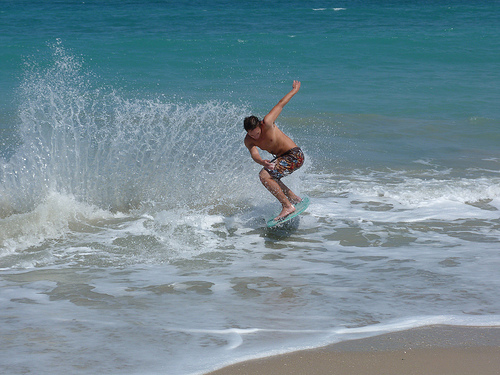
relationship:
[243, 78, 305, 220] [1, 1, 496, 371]
man surfing in ocean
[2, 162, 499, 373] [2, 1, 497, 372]
seafoam on water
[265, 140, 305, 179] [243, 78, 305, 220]
colorful trunks on man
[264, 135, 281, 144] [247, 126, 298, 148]
nipple on chest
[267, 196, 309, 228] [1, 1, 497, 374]
board on ocean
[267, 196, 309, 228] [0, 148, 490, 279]
board on waves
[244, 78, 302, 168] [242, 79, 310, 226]
arms of man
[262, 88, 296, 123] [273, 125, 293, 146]
arm behind back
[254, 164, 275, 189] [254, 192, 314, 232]
knee crouched on surfboard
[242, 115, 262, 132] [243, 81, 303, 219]
hair of man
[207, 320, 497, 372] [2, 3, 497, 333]
beach by ocean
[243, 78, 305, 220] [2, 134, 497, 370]
man on shallow water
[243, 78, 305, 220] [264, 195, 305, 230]
man on board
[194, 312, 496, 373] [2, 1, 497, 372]
edge of water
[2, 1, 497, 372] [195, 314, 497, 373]
water on sand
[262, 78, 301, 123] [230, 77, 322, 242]
arm of surfer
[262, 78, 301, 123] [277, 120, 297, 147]
arm extended in back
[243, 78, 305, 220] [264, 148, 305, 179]
man wearing colorful trunks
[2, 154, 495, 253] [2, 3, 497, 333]
wave in ocean